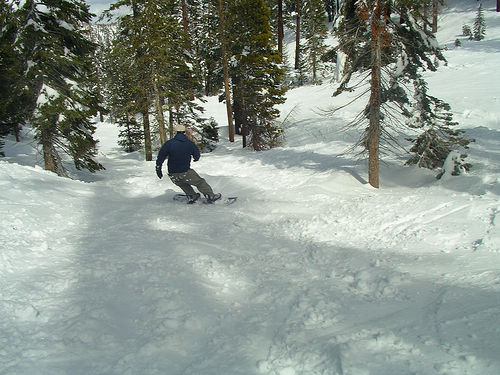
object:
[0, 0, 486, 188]
pine trees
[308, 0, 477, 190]
tree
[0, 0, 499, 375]
shadows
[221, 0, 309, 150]
clock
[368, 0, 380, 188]
brown trunk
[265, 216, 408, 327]
footprints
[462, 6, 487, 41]
pine tree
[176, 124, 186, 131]
hat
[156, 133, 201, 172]
hoodie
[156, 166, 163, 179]
glove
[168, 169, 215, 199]
pants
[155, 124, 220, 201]
man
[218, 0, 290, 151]
pine tree